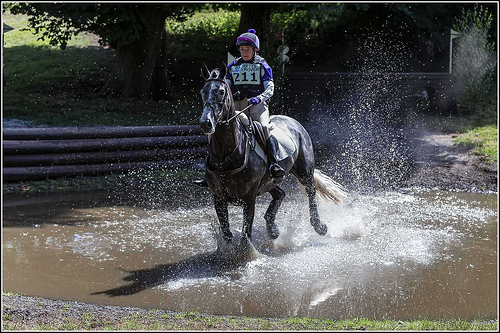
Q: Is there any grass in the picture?
A: Yes, there is grass.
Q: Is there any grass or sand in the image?
A: Yes, there is grass.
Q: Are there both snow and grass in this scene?
A: No, there is grass but no snow.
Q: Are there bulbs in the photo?
A: No, there are no bulbs.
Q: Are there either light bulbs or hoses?
A: No, there are no light bulbs or hoses.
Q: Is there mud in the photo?
A: Yes, there is mud.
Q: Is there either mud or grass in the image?
A: Yes, there is mud.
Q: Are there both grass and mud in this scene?
A: Yes, there are both mud and grass.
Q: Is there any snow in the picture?
A: No, there is no snow.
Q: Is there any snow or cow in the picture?
A: No, there are no snow or cows.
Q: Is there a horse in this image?
A: Yes, there is a horse.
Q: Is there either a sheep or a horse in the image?
A: Yes, there is a horse.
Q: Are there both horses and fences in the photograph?
A: Yes, there are both a horse and a fence.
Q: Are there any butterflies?
A: No, there are no butterflies.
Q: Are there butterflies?
A: No, there are no butterflies.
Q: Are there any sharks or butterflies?
A: No, there are no butterflies or sharks.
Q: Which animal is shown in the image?
A: The animal is a horse.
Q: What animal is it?
A: The animal is a horse.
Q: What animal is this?
A: That is a horse.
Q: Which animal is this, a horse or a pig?
A: That is a horse.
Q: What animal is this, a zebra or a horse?
A: This is a horse.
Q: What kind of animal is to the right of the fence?
A: The animal is a horse.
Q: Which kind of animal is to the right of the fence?
A: The animal is a horse.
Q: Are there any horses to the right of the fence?
A: Yes, there is a horse to the right of the fence.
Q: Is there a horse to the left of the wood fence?
A: No, the horse is to the right of the fence.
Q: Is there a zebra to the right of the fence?
A: No, there is a horse to the right of the fence.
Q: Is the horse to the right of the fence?
A: Yes, the horse is to the right of the fence.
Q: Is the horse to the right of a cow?
A: No, the horse is to the right of the fence.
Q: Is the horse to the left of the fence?
A: No, the horse is to the right of the fence.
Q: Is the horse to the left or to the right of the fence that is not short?
A: The horse is to the right of the fence.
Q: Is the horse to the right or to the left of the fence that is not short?
A: The horse is to the right of the fence.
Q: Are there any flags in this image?
A: Yes, there is a flag.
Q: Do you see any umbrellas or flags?
A: Yes, there is a flag.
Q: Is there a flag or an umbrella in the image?
A: Yes, there is a flag.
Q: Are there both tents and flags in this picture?
A: No, there is a flag but no tents.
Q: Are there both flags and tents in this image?
A: No, there is a flag but no tents.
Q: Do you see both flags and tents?
A: No, there is a flag but no tents.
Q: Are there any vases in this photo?
A: No, there are no vases.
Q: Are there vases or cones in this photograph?
A: No, there are no vases or cones.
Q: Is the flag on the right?
A: Yes, the flag is on the right of the image.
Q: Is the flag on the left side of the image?
A: No, the flag is on the right of the image.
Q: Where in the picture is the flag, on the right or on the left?
A: The flag is on the right of the image.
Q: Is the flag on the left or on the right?
A: The flag is on the right of the image.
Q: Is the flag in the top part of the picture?
A: Yes, the flag is in the top of the image.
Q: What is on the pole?
A: The flag is on the pole.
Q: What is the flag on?
A: The flag is on the pole.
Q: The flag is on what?
A: The flag is on the pole.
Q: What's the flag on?
A: The flag is on the pole.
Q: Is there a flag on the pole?
A: Yes, there is a flag on the pole.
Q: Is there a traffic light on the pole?
A: No, there is a flag on the pole.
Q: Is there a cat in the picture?
A: No, there are no cats.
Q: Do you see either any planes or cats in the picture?
A: No, there are no cats or planes.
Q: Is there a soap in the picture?
A: No, there are no soaps.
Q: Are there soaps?
A: No, there are no soaps.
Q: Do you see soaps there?
A: No, there are no soaps.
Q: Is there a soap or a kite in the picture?
A: No, there are no soaps or kites.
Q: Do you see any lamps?
A: No, there are no lamps.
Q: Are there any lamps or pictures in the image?
A: No, there are no lamps or pictures.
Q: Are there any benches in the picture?
A: No, there are no benches.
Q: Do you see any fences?
A: Yes, there is a fence.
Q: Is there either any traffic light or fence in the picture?
A: Yes, there is a fence.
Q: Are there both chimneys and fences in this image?
A: No, there is a fence but no chimneys.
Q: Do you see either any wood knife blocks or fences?
A: Yes, there is a wood fence.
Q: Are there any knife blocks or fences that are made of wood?
A: Yes, the fence is made of wood.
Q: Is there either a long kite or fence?
A: Yes, there is a long fence.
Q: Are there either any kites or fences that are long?
A: Yes, the fence is long.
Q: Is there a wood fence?
A: Yes, there is a fence that is made of wood.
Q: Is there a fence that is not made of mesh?
A: Yes, there is a fence that is made of wood.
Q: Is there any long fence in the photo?
A: Yes, there is a long fence.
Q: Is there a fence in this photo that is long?
A: Yes, there is a fence that is long.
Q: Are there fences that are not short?
A: Yes, there is a long fence.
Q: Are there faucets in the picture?
A: No, there are no faucets.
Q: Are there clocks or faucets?
A: No, there are no faucets or clocks.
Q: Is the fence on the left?
A: Yes, the fence is on the left of the image.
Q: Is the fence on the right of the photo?
A: No, the fence is on the left of the image.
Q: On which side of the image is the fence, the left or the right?
A: The fence is on the left of the image.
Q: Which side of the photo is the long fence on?
A: The fence is on the left of the image.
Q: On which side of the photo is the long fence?
A: The fence is on the left of the image.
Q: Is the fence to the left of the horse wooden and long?
A: Yes, the fence is wooden and long.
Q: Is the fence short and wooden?
A: No, the fence is wooden but long.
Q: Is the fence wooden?
A: Yes, the fence is wooden.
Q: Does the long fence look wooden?
A: Yes, the fence is wooden.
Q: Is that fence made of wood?
A: Yes, the fence is made of wood.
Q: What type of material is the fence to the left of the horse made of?
A: The fence is made of wood.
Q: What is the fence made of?
A: The fence is made of wood.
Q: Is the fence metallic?
A: No, the fence is wooden.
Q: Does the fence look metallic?
A: No, the fence is wooden.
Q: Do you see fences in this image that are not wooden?
A: No, there is a fence but it is wooden.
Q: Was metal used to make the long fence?
A: No, the fence is made of wood.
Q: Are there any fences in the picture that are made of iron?
A: No, there is a fence but it is made of wood.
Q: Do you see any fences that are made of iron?
A: No, there is a fence but it is made of wood.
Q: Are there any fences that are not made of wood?
A: No, there is a fence but it is made of wood.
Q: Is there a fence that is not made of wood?
A: No, there is a fence but it is made of wood.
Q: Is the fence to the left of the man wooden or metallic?
A: The fence is wooden.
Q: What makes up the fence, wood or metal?
A: The fence is made of wood.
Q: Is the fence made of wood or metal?
A: The fence is made of wood.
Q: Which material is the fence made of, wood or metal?
A: The fence is made of wood.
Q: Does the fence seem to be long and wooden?
A: Yes, the fence is long and wooden.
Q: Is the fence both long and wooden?
A: Yes, the fence is long and wooden.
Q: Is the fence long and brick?
A: No, the fence is long but wooden.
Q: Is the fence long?
A: Yes, the fence is long.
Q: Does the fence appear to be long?
A: Yes, the fence is long.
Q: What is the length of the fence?
A: The fence is long.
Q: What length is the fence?
A: The fence is long.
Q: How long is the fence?
A: The fence is long.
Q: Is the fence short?
A: No, the fence is long.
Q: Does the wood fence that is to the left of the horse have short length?
A: No, the fence is long.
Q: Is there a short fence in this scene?
A: No, there is a fence but it is long.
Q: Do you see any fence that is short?
A: No, there is a fence but it is long.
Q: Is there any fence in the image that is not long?
A: No, there is a fence but it is long.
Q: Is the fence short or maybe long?
A: The fence is long.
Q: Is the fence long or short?
A: The fence is long.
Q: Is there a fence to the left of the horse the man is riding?
A: Yes, there is a fence to the left of the horse.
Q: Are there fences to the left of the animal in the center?
A: Yes, there is a fence to the left of the horse.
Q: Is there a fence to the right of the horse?
A: No, the fence is to the left of the horse.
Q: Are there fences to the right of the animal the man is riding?
A: No, the fence is to the left of the horse.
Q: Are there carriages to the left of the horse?
A: No, there is a fence to the left of the horse.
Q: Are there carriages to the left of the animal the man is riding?
A: No, there is a fence to the left of the horse.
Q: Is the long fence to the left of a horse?
A: Yes, the fence is to the left of a horse.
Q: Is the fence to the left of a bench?
A: No, the fence is to the left of a horse.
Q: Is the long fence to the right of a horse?
A: No, the fence is to the left of a horse.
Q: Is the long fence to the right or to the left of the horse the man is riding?
A: The fence is to the left of the horse.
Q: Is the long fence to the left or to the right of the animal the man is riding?
A: The fence is to the left of the horse.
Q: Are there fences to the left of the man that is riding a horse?
A: Yes, there is a fence to the left of the man.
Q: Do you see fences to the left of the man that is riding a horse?
A: Yes, there is a fence to the left of the man.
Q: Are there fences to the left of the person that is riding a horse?
A: Yes, there is a fence to the left of the man.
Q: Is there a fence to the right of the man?
A: No, the fence is to the left of the man.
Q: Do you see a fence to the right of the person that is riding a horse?
A: No, the fence is to the left of the man.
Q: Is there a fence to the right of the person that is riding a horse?
A: No, the fence is to the left of the man.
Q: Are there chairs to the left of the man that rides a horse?
A: No, there is a fence to the left of the man.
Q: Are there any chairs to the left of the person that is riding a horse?
A: No, there is a fence to the left of the man.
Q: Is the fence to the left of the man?
A: Yes, the fence is to the left of the man.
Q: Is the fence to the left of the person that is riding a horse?
A: Yes, the fence is to the left of the man.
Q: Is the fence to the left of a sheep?
A: No, the fence is to the left of the man.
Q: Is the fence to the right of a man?
A: No, the fence is to the left of a man.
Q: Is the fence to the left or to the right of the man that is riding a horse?
A: The fence is to the left of the man.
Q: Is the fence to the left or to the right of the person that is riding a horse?
A: The fence is to the left of the man.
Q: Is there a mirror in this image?
A: No, there are no mirrors.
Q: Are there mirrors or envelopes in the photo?
A: No, there are no mirrors or envelopes.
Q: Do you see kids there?
A: No, there are no kids.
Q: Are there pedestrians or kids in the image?
A: No, there are no kids or pedestrians.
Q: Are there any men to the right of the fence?
A: Yes, there is a man to the right of the fence.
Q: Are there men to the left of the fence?
A: No, the man is to the right of the fence.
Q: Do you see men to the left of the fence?
A: No, the man is to the right of the fence.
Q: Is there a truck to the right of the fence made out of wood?
A: No, there is a man to the right of the fence.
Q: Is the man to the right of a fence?
A: Yes, the man is to the right of a fence.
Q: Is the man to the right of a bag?
A: No, the man is to the right of a fence.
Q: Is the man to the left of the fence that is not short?
A: No, the man is to the right of the fence.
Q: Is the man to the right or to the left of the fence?
A: The man is to the right of the fence.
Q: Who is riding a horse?
A: The man is riding a horse.